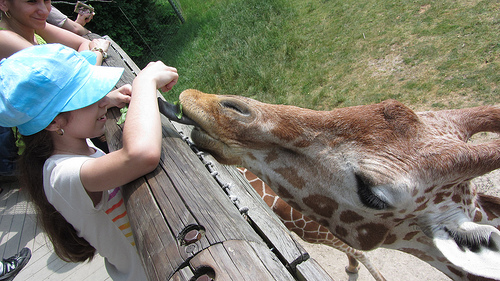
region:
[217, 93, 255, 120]
nostril on a giraffe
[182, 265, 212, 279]
bolt in a wooden fence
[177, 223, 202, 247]
bolt in a wooden fence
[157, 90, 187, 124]
black tongue of a giraffe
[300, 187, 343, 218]
brown spot on a giraffe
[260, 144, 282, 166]
brown spot on a giraffe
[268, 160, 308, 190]
brown spot on a giraffe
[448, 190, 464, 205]
brown spot on a giraffe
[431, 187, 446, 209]
brown spot on a giraffe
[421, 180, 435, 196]
brown spot on a giraffe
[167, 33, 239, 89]
patch of green grass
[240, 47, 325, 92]
patch of green grass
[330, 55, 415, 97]
patch of green grass with bare earth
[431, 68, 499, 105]
patch of green grass with bare earth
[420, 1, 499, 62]
patch of green grass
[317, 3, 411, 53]
patch of green grass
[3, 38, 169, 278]
girl wearing blue hat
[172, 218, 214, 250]
metal screw in wood fence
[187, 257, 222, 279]
metal screw in wood fence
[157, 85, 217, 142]
giraffe's long black tongue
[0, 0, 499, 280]
the grounds of a zoo exhibit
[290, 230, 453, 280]
a dirt ground below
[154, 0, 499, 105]
a field of green grass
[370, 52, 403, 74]
a small patch of dirt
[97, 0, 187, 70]
a metal fence by the trees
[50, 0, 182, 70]
a small wooded area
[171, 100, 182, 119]
a leaf eaten by a giraffe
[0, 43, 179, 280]
a little girl feeding a giraffe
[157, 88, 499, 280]
a giraffe eating a leaf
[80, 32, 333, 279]
a wooden railing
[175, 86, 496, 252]
the head of a giraffe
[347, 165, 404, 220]
the eye of a giraffe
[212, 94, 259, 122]
the nostril of a giraffe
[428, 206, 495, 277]
the ear of a giraffe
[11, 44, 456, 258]
a little girl feeding a giraffe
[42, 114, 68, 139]
an ear with an earring in it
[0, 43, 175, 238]
a little girl wearing a blue cap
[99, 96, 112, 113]
the nose of a little girl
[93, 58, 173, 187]
the arm of a little girl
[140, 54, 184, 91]
a hand of a little girl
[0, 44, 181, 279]
girl wearing light blue cap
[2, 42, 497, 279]
girl feeding giraffe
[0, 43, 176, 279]
girl with long brown hair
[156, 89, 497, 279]
giraffe with black tongue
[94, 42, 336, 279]
wooden fence between girl and giraffe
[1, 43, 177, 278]
girl next to person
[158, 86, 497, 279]
giraffe sticking out tongue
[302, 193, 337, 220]
rust colored spot on giraffe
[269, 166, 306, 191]
rust colored spot on giraffe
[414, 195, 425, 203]
rust colored spot on giraffe